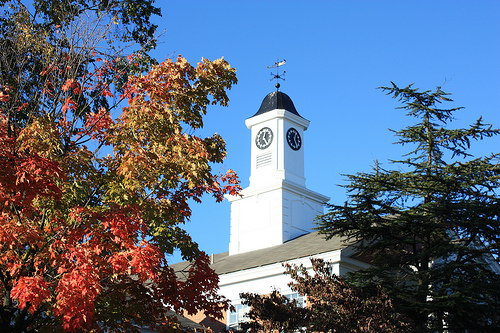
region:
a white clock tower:
[192, 52, 329, 272]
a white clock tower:
[221, 44, 317, 276]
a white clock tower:
[197, 37, 306, 274]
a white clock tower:
[195, 31, 319, 275]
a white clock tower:
[217, 64, 322, 299]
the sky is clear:
[313, 12, 414, 114]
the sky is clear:
[325, 61, 414, 164]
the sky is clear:
[305, 39, 390, 157]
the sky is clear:
[303, 8, 401, 203]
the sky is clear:
[313, 82, 399, 183]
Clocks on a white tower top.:
[255, 125, 306, 155]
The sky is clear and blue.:
[290, 0, 495, 100]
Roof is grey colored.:
[175, 225, 335, 275]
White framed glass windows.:
[220, 290, 310, 330]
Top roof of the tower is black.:
[240, 85, 305, 106]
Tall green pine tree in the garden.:
[375, 80, 495, 290]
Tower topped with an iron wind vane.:
[265, 50, 295, 80]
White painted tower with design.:
[283, 190, 323, 237]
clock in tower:
[245, 116, 273, 154]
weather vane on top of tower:
[248, 48, 303, 95]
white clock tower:
[247, 61, 305, 238]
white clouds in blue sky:
[178, 15, 216, 46]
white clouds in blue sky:
[255, 6, 309, 38]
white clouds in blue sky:
[321, 82, 381, 133]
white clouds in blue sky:
[314, 111, 344, 175]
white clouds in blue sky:
[425, 16, 467, 58]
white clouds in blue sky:
[334, 31, 411, 62]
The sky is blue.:
[343, 3, 495, 61]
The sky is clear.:
[333, 6, 489, 65]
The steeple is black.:
[248, 51, 308, 120]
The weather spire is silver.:
[266, 55, 290, 91]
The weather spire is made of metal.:
[267, 52, 296, 89]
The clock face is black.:
[256, 127, 274, 150]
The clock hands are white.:
[253, 124, 275, 149]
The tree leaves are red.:
[52, 260, 102, 331]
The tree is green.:
[323, 81, 498, 328]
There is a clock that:
[287, 124, 304, 170]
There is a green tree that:
[398, 110, 465, 242]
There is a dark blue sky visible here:
[331, 30, 343, 84]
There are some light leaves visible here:
[126, 117, 147, 218]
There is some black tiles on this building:
[315, 230, 325, 257]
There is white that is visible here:
[226, 173, 287, 243]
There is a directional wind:
[265, 53, 295, 98]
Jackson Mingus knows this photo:
[67, 29, 297, 321]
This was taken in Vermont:
[111, 25, 345, 255]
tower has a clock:
[254, 125, 276, 149]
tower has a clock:
[288, 125, 303, 152]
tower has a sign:
[271, 57, 286, 91]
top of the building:
[235, 43, 331, 115]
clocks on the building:
[216, 113, 321, 183]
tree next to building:
[342, 95, 486, 243]